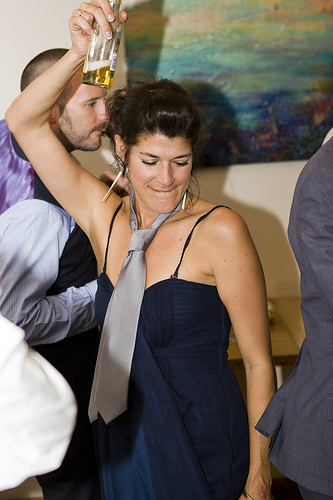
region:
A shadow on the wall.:
[120, 0, 170, 87]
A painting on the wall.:
[118, 0, 332, 168]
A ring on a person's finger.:
[76, 10, 84, 18]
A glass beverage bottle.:
[79, 0, 128, 88]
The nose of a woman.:
[154, 160, 176, 187]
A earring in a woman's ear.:
[102, 168, 122, 205]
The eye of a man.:
[84, 100, 98, 109]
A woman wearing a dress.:
[4, 0, 278, 499]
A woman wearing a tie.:
[3, 0, 277, 499]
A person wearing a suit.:
[253, 131, 331, 499]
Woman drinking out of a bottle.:
[5, 1, 281, 498]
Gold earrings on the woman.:
[90, 83, 192, 218]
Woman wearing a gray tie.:
[82, 79, 201, 429]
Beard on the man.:
[16, 44, 109, 156]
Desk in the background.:
[225, 293, 308, 394]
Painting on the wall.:
[113, 1, 332, 176]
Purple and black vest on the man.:
[0, 42, 112, 406]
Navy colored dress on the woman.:
[83, 52, 269, 498]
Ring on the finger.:
[74, 7, 93, 31]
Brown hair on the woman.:
[102, 76, 201, 218]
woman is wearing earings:
[100, 147, 224, 248]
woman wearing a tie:
[75, 93, 235, 416]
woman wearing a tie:
[92, 176, 200, 456]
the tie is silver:
[78, 179, 181, 432]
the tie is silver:
[98, 174, 221, 498]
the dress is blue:
[46, 228, 244, 498]